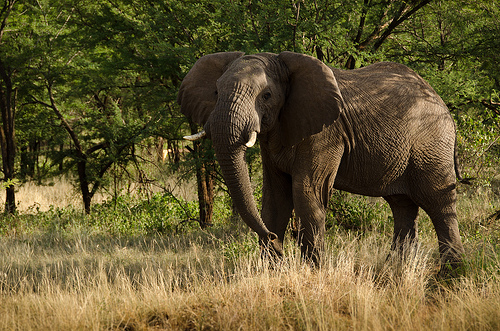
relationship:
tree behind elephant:
[25, 52, 152, 214] [177, 42, 474, 282]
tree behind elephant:
[149, 1, 246, 239] [177, 42, 474, 282]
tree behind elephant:
[260, 0, 412, 245] [177, 42, 474, 282]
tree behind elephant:
[405, 0, 497, 240] [177, 42, 474, 282]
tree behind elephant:
[0, 2, 26, 221] [177, 42, 474, 282]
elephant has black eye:
[177, 42, 474, 282] [262, 91, 273, 103]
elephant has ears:
[177, 42, 474, 282] [260, 42, 341, 123]